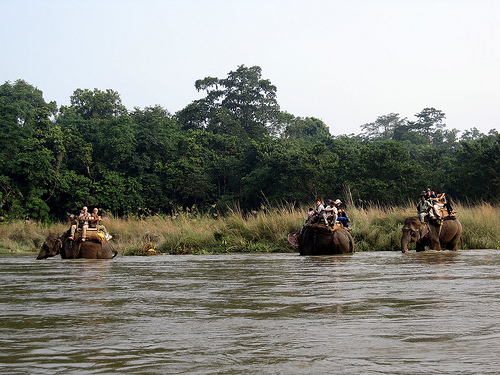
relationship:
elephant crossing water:
[400, 213, 466, 254] [2, 260, 499, 372]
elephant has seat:
[400, 213, 466, 254] [430, 211, 459, 220]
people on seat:
[414, 186, 449, 218] [430, 211, 459, 220]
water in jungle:
[2, 260, 499, 372] [4, 74, 500, 237]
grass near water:
[114, 217, 287, 245] [2, 260, 499, 372]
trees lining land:
[12, 129, 487, 198] [4, 199, 497, 228]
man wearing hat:
[79, 206, 90, 226] [81, 206, 89, 213]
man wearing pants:
[416, 194, 431, 225] [421, 211, 429, 222]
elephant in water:
[400, 213, 466, 254] [2, 260, 499, 372]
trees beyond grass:
[12, 129, 487, 198] [114, 217, 287, 245]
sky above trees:
[1, 0, 499, 77] [12, 129, 487, 198]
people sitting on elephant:
[414, 186, 449, 218] [400, 213, 466, 254]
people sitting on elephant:
[64, 207, 106, 239] [40, 228, 107, 260]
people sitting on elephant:
[300, 195, 348, 230] [296, 220, 353, 258]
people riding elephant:
[300, 195, 348, 230] [296, 220, 353, 258]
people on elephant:
[64, 207, 106, 239] [40, 228, 107, 260]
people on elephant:
[300, 195, 348, 230] [296, 220, 353, 258]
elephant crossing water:
[296, 220, 353, 258] [2, 260, 499, 372]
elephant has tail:
[40, 228, 107, 260] [109, 247, 122, 263]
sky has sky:
[1, 0, 499, 77] [1, 0, 500, 126]